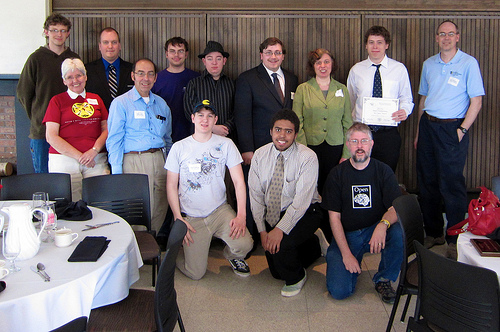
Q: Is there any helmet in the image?
A: No, there are no helmets.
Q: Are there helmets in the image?
A: No, there are no helmets.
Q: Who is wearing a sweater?
A: The man is wearing a sweater.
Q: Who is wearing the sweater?
A: The man is wearing a sweater.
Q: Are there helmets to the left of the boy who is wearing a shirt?
A: No, there is a man to the left of the boy.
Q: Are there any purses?
A: Yes, there is a purse.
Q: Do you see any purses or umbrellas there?
A: Yes, there is a purse.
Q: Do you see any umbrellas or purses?
A: Yes, there is a purse.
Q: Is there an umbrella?
A: No, there are no umbrellas.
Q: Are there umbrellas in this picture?
A: No, there are no umbrellas.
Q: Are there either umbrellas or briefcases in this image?
A: No, there are no umbrellas or briefcases.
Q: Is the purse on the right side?
A: Yes, the purse is on the right of the image.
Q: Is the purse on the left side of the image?
A: No, the purse is on the right of the image.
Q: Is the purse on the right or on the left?
A: The purse is on the right of the image.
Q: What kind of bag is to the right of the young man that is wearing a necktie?
A: The bag is a purse.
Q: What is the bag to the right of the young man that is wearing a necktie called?
A: The bag is a purse.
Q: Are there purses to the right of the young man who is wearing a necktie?
A: Yes, there is a purse to the right of the man.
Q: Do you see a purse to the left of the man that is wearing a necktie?
A: No, the purse is to the right of the man.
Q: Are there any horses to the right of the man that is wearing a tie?
A: No, there is a purse to the right of the man.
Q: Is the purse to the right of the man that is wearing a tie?
A: Yes, the purse is to the right of the man.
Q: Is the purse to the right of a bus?
A: No, the purse is to the right of the man.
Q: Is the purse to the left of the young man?
A: No, the purse is to the right of the man.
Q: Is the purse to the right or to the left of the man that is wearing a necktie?
A: The purse is to the right of the man.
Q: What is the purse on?
A: The purse is on the table.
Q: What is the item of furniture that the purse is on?
A: The piece of furniture is a table.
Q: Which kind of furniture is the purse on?
A: The purse is on the table.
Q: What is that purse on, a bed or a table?
A: The purse is on a table.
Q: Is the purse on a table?
A: Yes, the purse is on a table.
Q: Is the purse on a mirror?
A: No, the purse is on a table.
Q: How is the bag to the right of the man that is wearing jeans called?
A: The bag is a purse.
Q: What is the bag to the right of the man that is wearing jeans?
A: The bag is a purse.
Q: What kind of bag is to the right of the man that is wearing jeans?
A: The bag is a purse.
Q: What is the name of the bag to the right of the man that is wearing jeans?
A: The bag is a purse.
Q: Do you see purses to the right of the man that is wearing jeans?
A: Yes, there is a purse to the right of the man.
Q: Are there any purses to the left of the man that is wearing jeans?
A: No, the purse is to the right of the man.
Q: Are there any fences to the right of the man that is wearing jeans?
A: No, there is a purse to the right of the man.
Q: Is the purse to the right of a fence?
A: No, the purse is to the right of the man.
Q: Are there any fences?
A: No, there are no fences.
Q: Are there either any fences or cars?
A: No, there are no fences or cars.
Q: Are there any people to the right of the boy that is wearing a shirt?
A: Yes, there are people to the right of the boy.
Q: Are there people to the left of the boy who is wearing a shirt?
A: No, the people are to the right of the boy.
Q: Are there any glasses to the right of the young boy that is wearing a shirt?
A: No, there are people to the right of the boy.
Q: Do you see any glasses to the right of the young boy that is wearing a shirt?
A: No, there are people to the right of the boy.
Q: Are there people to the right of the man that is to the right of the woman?
A: Yes, there are people to the right of the man.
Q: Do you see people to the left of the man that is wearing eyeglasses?
A: No, the people are to the right of the man.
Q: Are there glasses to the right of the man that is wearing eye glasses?
A: No, there are people to the right of the man.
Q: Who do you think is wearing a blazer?
A: The people are wearing a blazer.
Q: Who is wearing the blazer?
A: The people are wearing a blazer.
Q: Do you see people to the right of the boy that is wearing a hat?
A: Yes, there are people to the right of the boy.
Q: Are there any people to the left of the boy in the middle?
A: No, the people are to the right of the boy.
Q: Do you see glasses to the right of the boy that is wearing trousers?
A: No, there are people to the right of the boy.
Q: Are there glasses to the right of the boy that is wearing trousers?
A: No, there are people to the right of the boy.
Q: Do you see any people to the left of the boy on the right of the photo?
A: Yes, there are people to the left of the boy.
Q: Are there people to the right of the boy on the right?
A: No, the people are to the left of the boy.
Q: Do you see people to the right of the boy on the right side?
A: No, the people are to the left of the boy.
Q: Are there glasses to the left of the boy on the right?
A: No, there are people to the left of the boy.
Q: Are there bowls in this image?
A: No, there are no bowls.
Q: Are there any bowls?
A: No, there are no bowls.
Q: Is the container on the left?
A: Yes, the container is on the left of the image.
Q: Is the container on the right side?
A: No, the container is on the left of the image.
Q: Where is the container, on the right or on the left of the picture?
A: The container is on the left of the image.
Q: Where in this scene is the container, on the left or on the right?
A: The container is on the left of the image.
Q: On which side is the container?
A: The container is on the left of the image.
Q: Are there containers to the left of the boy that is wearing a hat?
A: Yes, there is a container to the left of the boy.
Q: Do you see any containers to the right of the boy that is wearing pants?
A: No, the container is to the left of the boy.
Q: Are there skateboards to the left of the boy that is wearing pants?
A: No, there is a container to the left of the boy.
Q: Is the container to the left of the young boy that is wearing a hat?
A: Yes, the container is to the left of the boy.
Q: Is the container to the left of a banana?
A: No, the container is to the left of the boy.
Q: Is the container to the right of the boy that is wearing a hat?
A: No, the container is to the left of the boy.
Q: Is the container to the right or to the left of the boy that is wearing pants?
A: The container is to the left of the boy.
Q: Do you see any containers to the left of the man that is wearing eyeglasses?
A: Yes, there is a container to the left of the man.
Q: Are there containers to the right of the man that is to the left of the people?
A: No, the container is to the left of the man.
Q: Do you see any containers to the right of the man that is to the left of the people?
A: No, the container is to the left of the man.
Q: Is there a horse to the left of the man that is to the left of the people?
A: No, there is a container to the left of the man.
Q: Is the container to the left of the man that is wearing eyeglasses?
A: Yes, the container is to the left of the man.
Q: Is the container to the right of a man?
A: No, the container is to the left of a man.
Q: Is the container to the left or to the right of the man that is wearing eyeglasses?
A: The container is to the left of the man.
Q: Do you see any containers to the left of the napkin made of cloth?
A: Yes, there is a container to the left of the napkin.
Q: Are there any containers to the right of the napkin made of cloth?
A: No, the container is to the left of the napkin.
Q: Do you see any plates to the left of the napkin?
A: No, there is a container to the left of the napkin.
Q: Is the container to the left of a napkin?
A: Yes, the container is to the left of a napkin.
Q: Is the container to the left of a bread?
A: No, the container is to the left of a napkin.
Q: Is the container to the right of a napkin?
A: No, the container is to the left of a napkin.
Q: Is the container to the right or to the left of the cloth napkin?
A: The container is to the left of the napkin.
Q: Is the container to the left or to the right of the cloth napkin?
A: The container is to the left of the napkin.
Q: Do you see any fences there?
A: No, there are no fences.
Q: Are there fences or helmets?
A: No, there are no fences or helmets.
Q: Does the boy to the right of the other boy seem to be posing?
A: Yes, the boy is posing.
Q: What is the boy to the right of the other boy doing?
A: The boy is posing.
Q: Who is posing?
A: The boy is posing.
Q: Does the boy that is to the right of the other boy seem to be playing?
A: No, the boy is posing.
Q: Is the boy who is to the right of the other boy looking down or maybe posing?
A: The boy is posing.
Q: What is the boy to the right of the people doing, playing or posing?
A: The boy is posing.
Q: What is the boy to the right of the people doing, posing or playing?
A: The boy is posing.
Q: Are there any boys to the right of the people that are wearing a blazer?
A: Yes, there is a boy to the right of the people.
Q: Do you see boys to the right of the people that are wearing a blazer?
A: Yes, there is a boy to the right of the people.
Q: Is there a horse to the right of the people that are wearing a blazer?
A: No, there is a boy to the right of the people.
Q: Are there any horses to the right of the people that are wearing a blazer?
A: No, there is a boy to the right of the people.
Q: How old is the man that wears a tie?
A: The man is young.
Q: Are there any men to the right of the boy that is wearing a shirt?
A: Yes, there is a man to the right of the boy.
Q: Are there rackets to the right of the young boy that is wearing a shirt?
A: No, there is a man to the right of the boy.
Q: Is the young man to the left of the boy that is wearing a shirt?
A: No, the man is to the right of the boy.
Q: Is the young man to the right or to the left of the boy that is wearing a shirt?
A: The man is to the right of the boy.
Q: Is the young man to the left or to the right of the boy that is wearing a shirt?
A: The man is to the right of the boy.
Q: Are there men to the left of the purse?
A: Yes, there is a man to the left of the purse.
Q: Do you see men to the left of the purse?
A: Yes, there is a man to the left of the purse.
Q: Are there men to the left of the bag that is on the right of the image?
A: Yes, there is a man to the left of the purse.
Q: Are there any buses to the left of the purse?
A: No, there is a man to the left of the purse.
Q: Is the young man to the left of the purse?
A: Yes, the man is to the left of the purse.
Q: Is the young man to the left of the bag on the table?
A: Yes, the man is to the left of the purse.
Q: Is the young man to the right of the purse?
A: No, the man is to the left of the purse.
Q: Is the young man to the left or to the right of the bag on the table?
A: The man is to the left of the purse.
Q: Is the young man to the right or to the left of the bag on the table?
A: The man is to the left of the purse.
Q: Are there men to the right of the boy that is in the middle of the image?
A: Yes, there is a man to the right of the boy.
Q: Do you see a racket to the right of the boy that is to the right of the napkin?
A: No, there is a man to the right of the boy.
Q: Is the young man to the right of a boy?
A: Yes, the man is to the right of a boy.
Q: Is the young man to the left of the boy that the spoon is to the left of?
A: No, the man is to the right of the boy.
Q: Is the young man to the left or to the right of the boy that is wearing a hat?
A: The man is to the right of the boy.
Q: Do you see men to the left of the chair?
A: Yes, there is a man to the left of the chair.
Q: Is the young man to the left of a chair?
A: Yes, the man is to the left of a chair.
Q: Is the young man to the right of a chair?
A: No, the man is to the left of a chair.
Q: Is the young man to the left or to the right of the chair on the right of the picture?
A: The man is to the left of the chair.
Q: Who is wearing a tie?
A: The man is wearing a tie.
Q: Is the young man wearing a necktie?
A: Yes, the man is wearing a necktie.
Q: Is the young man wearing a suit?
A: No, the man is wearing a necktie.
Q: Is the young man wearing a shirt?
A: Yes, the man is wearing a shirt.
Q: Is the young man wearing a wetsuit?
A: No, the man is wearing a shirt.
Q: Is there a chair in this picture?
A: Yes, there is a chair.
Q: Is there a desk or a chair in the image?
A: Yes, there is a chair.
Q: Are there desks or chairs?
A: Yes, there is a chair.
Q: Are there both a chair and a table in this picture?
A: Yes, there are both a chair and a table.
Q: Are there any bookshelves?
A: No, there are no bookshelves.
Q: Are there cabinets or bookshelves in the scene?
A: No, there are no bookshelves or cabinets.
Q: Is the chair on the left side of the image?
A: No, the chair is on the right of the image.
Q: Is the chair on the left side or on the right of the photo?
A: The chair is on the right of the image.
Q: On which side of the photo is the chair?
A: The chair is on the right of the image.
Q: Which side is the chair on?
A: The chair is on the right of the image.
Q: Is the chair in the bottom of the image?
A: Yes, the chair is in the bottom of the image.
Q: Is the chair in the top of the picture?
A: No, the chair is in the bottom of the image.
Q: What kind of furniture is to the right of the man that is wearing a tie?
A: The piece of furniture is a chair.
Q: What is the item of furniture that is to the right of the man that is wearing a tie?
A: The piece of furniture is a chair.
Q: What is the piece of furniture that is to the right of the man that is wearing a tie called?
A: The piece of furniture is a chair.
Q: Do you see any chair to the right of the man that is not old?
A: Yes, there is a chair to the right of the man.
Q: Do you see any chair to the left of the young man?
A: No, the chair is to the right of the man.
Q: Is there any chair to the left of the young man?
A: No, the chair is to the right of the man.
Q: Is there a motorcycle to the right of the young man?
A: No, there is a chair to the right of the man.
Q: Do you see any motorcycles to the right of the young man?
A: No, there is a chair to the right of the man.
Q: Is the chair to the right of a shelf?
A: No, the chair is to the right of a man.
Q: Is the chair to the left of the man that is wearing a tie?
A: No, the chair is to the right of the man.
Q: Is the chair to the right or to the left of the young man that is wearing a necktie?
A: The chair is to the right of the man.